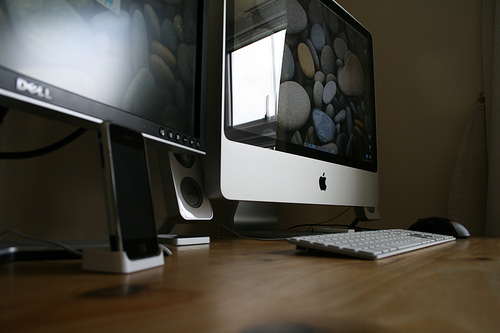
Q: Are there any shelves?
A: No, there are no shelves.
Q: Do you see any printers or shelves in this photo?
A: No, there are no shelves or printers.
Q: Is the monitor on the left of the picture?
A: Yes, the monitor is on the left of the image.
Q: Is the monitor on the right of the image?
A: No, the monitor is on the left of the image.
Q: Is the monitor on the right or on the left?
A: The monitor is on the left of the image.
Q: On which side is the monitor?
A: The monitor is on the left of the image.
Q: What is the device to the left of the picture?
A: The device is a monitor.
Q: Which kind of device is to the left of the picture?
A: The device is a monitor.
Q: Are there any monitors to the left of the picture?
A: Yes, there is a monitor to the left of the picture.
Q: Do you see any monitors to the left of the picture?
A: Yes, there is a monitor to the left of the picture.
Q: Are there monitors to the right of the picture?
A: No, the monitor is to the left of the picture.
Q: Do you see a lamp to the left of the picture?
A: No, there is a monitor to the left of the picture.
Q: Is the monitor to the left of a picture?
A: Yes, the monitor is to the left of a picture.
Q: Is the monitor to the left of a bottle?
A: No, the monitor is to the left of a picture.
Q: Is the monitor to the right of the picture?
A: No, the monitor is to the left of the picture.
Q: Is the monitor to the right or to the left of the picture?
A: The monitor is to the left of the picture.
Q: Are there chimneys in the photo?
A: No, there are no chimneys.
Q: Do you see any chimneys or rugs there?
A: No, there are no chimneys or rugs.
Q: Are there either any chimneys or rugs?
A: No, there are no chimneys or rugs.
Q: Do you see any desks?
A: Yes, there is a desk.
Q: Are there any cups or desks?
A: Yes, there is a desk.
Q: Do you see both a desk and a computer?
A: Yes, there are both a desk and a computer.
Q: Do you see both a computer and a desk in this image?
A: Yes, there are both a desk and a computer.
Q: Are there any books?
A: No, there are no books.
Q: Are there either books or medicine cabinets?
A: No, there are no books or medicine cabinets.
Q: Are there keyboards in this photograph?
A: Yes, there is a keyboard.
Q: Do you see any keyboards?
A: Yes, there is a keyboard.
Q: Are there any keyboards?
A: Yes, there is a keyboard.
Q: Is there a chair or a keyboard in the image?
A: Yes, there is a keyboard.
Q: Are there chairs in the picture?
A: No, there are no chairs.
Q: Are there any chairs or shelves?
A: No, there are no chairs or shelves.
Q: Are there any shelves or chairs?
A: No, there are no chairs or shelves.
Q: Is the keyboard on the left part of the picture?
A: No, the keyboard is on the right of the image.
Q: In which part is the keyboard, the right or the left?
A: The keyboard is on the right of the image.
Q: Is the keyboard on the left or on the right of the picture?
A: The keyboard is on the right of the image.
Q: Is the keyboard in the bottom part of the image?
A: Yes, the keyboard is in the bottom of the image.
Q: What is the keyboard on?
A: The keyboard is on the desk.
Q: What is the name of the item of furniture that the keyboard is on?
A: The piece of furniture is a desk.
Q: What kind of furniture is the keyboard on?
A: The keyboard is on the desk.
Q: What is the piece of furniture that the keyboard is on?
A: The piece of furniture is a desk.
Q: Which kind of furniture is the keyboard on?
A: The keyboard is on the desk.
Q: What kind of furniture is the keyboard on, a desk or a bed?
A: The keyboard is on a desk.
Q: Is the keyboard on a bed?
A: No, the keyboard is on the desk.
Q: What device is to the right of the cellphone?
A: The device is a keyboard.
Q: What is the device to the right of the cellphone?
A: The device is a keyboard.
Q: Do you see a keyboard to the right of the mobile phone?
A: Yes, there is a keyboard to the right of the mobile phone.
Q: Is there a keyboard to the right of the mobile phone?
A: Yes, there is a keyboard to the right of the mobile phone.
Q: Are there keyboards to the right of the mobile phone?
A: Yes, there is a keyboard to the right of the mobile phone.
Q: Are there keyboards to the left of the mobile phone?
A: No, the keyboard is to the right of the mobile phone.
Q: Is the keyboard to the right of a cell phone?
A: Yes, the keyboard is to the right of a cell phone.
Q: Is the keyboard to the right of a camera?
A: No, the keyboard is to the right of a cell phone.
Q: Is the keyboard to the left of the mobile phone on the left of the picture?
A: No, the keyboard is to the right of the cell phone.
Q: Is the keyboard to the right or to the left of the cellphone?
A: The keyboard is to the right of the cellphone.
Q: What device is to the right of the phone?
A: The device is a keyboard.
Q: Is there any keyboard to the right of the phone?
A: Yes, there is a keyboard to the right of the phone.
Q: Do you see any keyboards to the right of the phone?
A: Yes, there is a keyboard to the right of the phone.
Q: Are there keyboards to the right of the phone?
A: Yes, there is a keyboard to the right of the phone.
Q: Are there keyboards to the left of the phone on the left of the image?
A: No, the keyboard is to the right of the phone.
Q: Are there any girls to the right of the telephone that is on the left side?
A: No, there is a keyboard to the right of the telephone.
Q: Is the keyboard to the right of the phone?
A: Yes, the keyboard is to the right of the phone.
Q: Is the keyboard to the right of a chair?
A: No, the keyboard is to the right of the phone.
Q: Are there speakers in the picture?
A: Yes, there is a speaker.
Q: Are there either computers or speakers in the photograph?
A: Yes, there is a speaker.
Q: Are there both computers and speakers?
A: Yes, there are both a speaker and a computer.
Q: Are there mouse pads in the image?
A: No, there are no mouse pads.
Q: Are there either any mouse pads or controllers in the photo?
A: No, there are no mouse pads or controllers.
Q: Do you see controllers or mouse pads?
A: No, there are no mouse pads or controllers.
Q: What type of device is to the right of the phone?
A: The device is a speaker.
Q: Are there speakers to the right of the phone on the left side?
A: Yes, there is a speaker to the right of the phone.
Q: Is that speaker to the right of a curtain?
A: No, the speaker is to the right of the phone.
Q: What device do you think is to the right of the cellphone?
A: The device is a speaker.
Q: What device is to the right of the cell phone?
A: The device is a speaker.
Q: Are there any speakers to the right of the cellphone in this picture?
A: Yes, there is a speaker to the right of the cellphone.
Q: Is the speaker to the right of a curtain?
A: No, the speaker is to the right of a cell phone.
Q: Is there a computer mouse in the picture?
A: Yes, there is a computer mouse.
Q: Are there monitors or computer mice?
A: Yes, there is a computer mouse.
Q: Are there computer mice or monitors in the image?
A: Yes, there is a computer mouse.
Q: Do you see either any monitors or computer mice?
A: Yes, there is a computer mouse.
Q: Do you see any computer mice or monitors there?
A: Yes, there is a computer mouse.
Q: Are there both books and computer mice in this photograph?
A: No, there is a computer mouse but no books.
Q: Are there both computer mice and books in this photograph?
A: No, there is a computer mouse but no books.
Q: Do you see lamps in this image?
A: No, there are no lamps.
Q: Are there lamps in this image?
A: No, there are no lamps.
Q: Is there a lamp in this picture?
A: No, there are no lamps.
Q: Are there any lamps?
A: No, there are no lamps.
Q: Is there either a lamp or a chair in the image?
A: No, there are no lamps or chairs.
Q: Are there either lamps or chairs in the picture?
A: No, there are no lamps or chairs.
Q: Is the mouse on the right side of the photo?
A: Yes, the mouse is on the right of the image.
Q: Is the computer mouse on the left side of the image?
A: No, the computer mouse is on the right of the image.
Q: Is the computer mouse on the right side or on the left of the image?
A: The computer mouse is on the right of the image.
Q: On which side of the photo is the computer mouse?
A: The computer mouse is on the right of the image.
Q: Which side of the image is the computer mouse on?
A: The computer mouse is on the right of the image.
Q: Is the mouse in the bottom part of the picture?
A: Yes, the mouse is in the bottom of the image.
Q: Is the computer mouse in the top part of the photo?
A: No, the computer mouse is in the bottom of the image.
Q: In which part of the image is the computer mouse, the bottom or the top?
A: The computer mouse is in the bottom of the image.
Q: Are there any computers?
A: Yes, there is a computer.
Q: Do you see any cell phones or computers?
A: Yes, there is a computer.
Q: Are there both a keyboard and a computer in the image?
A: Yes, there are both a computer and a keyboard.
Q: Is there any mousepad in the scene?
A: No, there are no mouse pads.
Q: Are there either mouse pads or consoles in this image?
A: No, there are no mouse pads or consoles.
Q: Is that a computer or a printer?
A: That is a computer.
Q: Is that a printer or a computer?
A: That is a computer.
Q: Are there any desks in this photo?
A: Yes, there is a desk.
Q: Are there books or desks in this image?
A: Yes, there is a desk.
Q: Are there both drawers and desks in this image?
A: No, there is a desk but no drawers.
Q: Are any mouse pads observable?
A: No, there are no mouse pads.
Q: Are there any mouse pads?
A: No, there are no mouse pads.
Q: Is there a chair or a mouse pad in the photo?
A: No, there are no mouse pads or chairs.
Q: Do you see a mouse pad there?
A: No, there are no mouse pads.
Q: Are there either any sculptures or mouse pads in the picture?
A: No, there are no mouse pads or sculptures.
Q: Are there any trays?
A: No, there are no trays.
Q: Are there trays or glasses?
A: No, there are no trays or glasses.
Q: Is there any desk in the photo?
A: Yes, there is a desk.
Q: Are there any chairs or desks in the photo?
A: Yes, there is a desk.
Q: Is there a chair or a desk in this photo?
A: Yes, there is a desk.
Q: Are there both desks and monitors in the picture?
A: Yes, there are both a desk and a monitor.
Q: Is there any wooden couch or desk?
A: Yes, there is a wood desk.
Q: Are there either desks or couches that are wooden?
A: Yes, the desk is wooden.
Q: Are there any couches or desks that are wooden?
A: Yes, the desk is wooden.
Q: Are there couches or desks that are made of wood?
A: Yes, the desk is made of wood.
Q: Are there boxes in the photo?
A: No, there are no boxes.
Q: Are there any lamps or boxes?
A: No, there are no boxes or lamps.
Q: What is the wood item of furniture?
A: The piece of furniture is a desk.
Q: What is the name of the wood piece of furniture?
A: The piece of furniture is a desk.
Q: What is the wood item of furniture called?
A: The piece of furniture is a desk.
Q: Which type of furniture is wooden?
A: The furniture is a desk.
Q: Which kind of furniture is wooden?
A: The furniture is a desk.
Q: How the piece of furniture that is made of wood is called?
A: The piece of furniture is a desk.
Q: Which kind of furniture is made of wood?
A: The furniture is a desk.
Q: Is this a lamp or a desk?
A: This is a desk.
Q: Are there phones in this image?
A: Yes, there is a phone.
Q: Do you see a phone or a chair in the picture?
A: Yes, there is a phone.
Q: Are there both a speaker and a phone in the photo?
A: Yes, there are both a phone and a speaker.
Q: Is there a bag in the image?
A: No, there are no bags.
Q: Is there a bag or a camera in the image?
A: No, there are no bags or cameras.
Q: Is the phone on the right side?
A: No, the phone is on the left of the image.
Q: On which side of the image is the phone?
A: The phone is on the left of the image.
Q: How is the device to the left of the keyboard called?
A: The device is a phone.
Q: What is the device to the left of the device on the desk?
A: The device is a phone.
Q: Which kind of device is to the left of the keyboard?
A: The device is a phone.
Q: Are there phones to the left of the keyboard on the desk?
A: Yes, there is a phone to the left of the keyboard.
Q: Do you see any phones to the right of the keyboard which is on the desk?
A: No, the phone is to the left of the keyboard.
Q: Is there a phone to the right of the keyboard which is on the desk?
A: No, the phone is to the left of the keyboard.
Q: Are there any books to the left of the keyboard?
A: No, there is a phone to the left of the keyboard.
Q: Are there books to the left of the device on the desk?
A: No, there is a phone to the left of the keyboard.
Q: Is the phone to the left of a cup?
A: No, the phone is to the left of a keyboard.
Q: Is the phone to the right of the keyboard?
A: No, the phone is to the left of the keyboard.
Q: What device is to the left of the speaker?
A: The device is a phone.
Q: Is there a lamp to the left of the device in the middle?
A: No, there is a phone to the left of the speaker.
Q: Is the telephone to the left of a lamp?
A: No, the telephone is to the left of the speaker.